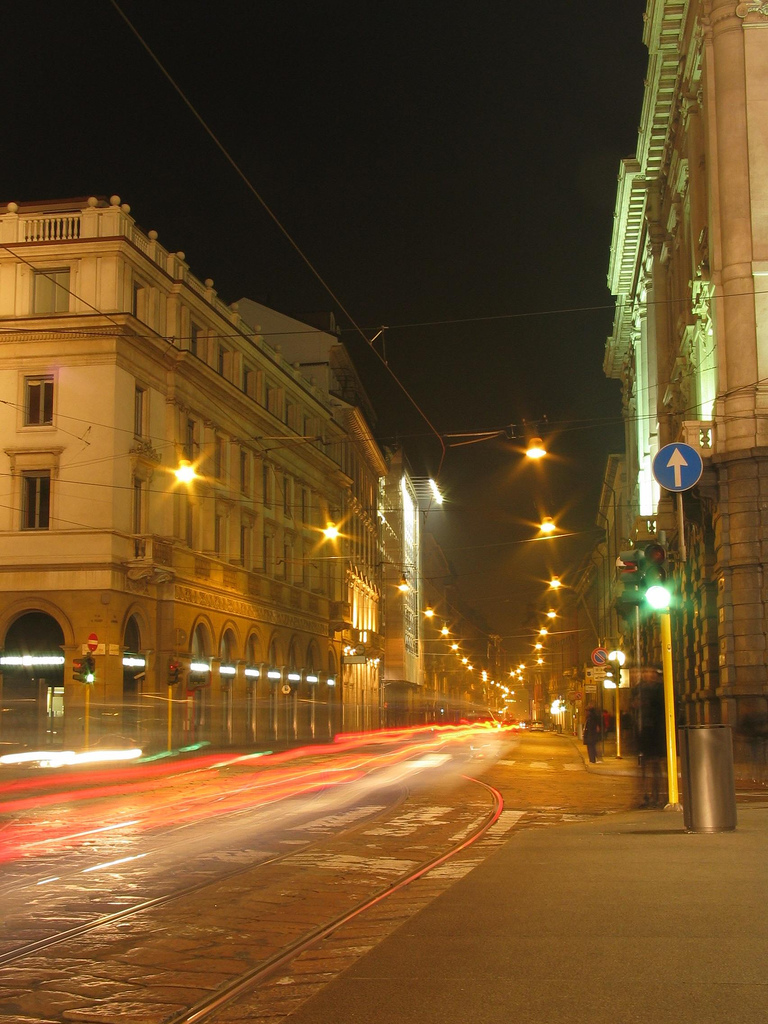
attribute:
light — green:
[638, 580, 680, 812]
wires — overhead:
[110, 4, 588, 501]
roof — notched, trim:
[605, 7, 689, 315]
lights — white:
[425, 475, 443, 507]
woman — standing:
[582, 705, 600, 767]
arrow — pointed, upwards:
[665, 446, 684, 488]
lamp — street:
[620, 537, 683, 816]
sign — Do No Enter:
[85, 633, 95, 649]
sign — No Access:
[591, 646, 606, 663]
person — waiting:
[582, 704, 599, 761]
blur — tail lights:
[1, 715, 527, 863]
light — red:
[5, 725, 507, 863]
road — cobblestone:
[5, 719, 560, 1020]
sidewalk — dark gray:
[277, 821, 765, 1020]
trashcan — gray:
[678, 723, 738, 831]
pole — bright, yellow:
[658, 610, 688, 812]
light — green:
[642, 584, 668, 613]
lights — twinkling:
[522, 432, 569, 671]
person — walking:
[580, 702, 600, 764]